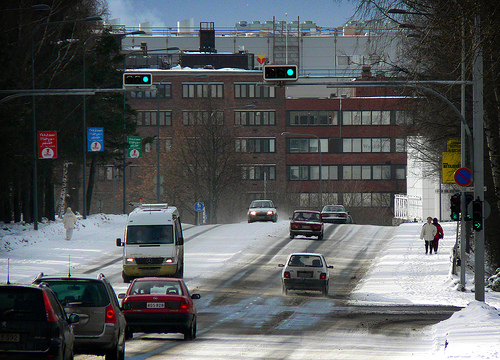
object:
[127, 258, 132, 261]
headlights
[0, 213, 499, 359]
snow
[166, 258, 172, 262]
headlights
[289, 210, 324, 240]
cars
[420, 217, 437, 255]
people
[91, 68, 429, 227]
building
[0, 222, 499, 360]
ground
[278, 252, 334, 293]
car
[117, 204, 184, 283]
truck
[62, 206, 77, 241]
pedestrian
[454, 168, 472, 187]
sign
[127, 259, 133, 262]
van's headlights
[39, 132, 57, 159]
sign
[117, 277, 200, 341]
car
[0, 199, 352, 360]
city traffic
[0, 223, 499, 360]
city street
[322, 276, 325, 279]
cars headlights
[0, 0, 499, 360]
city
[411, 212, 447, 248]
people are walking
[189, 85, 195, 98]
windows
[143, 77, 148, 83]
green lights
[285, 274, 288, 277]
red lights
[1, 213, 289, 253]
black shadow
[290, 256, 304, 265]
driver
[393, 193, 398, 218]
white lines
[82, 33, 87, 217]
pole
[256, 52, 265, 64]
flag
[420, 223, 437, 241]
coat